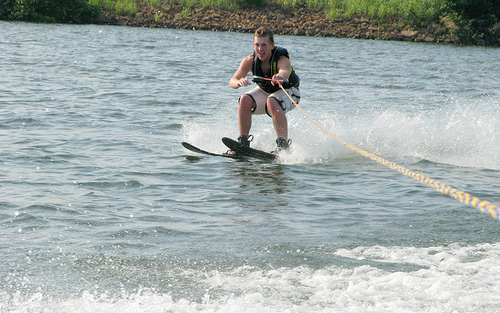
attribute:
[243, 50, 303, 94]
jacket — life  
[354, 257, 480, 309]
wake — foamy 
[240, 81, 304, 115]
trunks — white swim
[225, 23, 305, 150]
man — waterskiing , skiing outside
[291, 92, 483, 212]
rope — blue  , yellow  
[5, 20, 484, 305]
adventure — water skiing 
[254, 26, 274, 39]
hair — brown 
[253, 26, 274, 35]
hair — Man's , curly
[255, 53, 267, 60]
teeth — white  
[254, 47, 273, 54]
teeth — Man's , straight 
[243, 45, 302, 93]
vest — life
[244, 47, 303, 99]
vest — black, Man's life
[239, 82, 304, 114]
shorts — white  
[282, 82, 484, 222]
rope — ski, Tow 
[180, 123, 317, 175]
ski — black , Man's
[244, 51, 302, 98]
jacket — life 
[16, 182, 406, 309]
water — body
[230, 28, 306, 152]
man — bent down